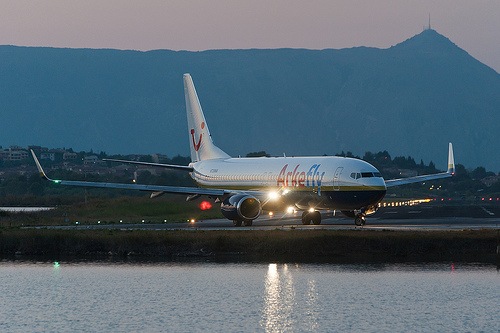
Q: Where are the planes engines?
A: Underneath the wings.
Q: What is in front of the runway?
A: A large body of water.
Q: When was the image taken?
A: In the morning.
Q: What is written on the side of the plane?
A: Arkefly.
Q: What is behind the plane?
A: A small city and a mountain.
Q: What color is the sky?
A: Grey.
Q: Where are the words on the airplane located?
A: On the side.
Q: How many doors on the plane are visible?
A: One.